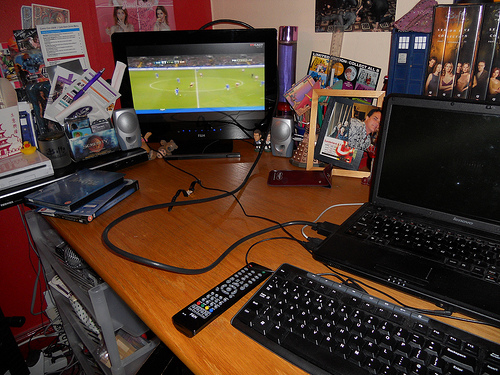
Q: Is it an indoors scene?
A: Yes, it is indoors.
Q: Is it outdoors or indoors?
A: It is indoors.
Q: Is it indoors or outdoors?
A: It is indoors.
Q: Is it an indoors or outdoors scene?
A: It is indoors.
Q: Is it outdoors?
A: No, it is indoors.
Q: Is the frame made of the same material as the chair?
A: No, the frame is made of wood and the chair is made of metal.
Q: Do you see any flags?
A: No, there are no flags.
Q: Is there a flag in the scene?
A: No, there are no flags.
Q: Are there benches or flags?
A: No, there are no flags or benches.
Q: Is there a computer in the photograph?
A: Yes, there is a computer.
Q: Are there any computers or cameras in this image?
A: Yes, there is a computer.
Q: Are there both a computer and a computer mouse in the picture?
A: No, there is a computer but no computer mice.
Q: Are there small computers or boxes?
A: Yes, there is a small computer.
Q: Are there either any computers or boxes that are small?
A: Yes, the computer is small.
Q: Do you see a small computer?
A: Yes, there is a small computer.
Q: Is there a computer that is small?
A: Yes, there is a computer that is small.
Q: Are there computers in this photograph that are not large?
A: Yes, there is a small computer.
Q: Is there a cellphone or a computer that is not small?
A: No, there is a computer but it is small.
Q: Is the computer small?
A: Yes, the computer is small.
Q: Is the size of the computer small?
A: Yes, the computer is small.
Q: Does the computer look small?
A: Yes, the computer is small.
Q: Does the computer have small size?
A: Yes, the computer is small.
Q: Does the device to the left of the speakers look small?
A: Yes, the computer is small.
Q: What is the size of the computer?
A: The computer is small.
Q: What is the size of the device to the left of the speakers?
A: The computer is small.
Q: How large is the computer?
A: The computer is small.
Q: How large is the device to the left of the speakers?
A: The computer is small.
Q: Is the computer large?
A: No, the computer is small.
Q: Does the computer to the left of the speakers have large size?
A: No, the computer is small.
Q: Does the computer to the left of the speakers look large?
A: No, the computer is small.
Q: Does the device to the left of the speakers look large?
A: No, the computer is small.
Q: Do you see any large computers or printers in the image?
A: No, there is a computer but it is small.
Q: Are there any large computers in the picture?
A: No, there is a computer but it is small.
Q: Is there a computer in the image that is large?
A: No, there is a computer but it is small.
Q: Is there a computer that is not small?
A: No, there is a computer but it is small.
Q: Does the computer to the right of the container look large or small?
A: The computer is small.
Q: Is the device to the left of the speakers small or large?
A: The computer is small.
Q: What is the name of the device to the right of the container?
A: The device is a computer.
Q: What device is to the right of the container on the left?
A: The device is a computer.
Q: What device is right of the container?
A: The device is a computer.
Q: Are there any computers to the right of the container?
A: Yes, there is a computer to the right of the container.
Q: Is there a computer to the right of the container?
A: Yes, there is a computer to the right of the container.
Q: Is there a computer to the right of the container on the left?
A: Yes, there is a computer to the right of the container.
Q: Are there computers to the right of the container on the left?
A: Yes, there is a computer to the right of the container.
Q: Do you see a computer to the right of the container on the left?
A: Yes, there is a computer to the right of the container.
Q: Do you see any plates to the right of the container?
A: No, there is a computer to the right of the container.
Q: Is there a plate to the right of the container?
A: No, there is a computer to the right of the container.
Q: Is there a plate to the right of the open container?
A: No, there is a computer to the right of the container.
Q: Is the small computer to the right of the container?
A: Yes, the computer is to the right of the container.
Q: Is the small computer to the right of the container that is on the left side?
A: Yes, the computer is to the right of the container.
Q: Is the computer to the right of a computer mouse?
A: No, the computer is to the right of the container.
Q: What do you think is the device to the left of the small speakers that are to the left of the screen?
A: The device is a computer.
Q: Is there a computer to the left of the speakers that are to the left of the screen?
A: Yes, there is a computer to the left of the speakers.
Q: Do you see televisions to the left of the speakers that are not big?
A: No, there is a computer to the left of the speakers.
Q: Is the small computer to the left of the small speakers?
A: Yes, the computer is to the left of the speakers.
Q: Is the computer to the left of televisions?
A: No, the computer is to the left of the speakers.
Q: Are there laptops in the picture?
A: Yes, there is a laptop.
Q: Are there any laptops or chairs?
A: Yes, there is a laptop.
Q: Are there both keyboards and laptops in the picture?
A: Yes, there are both a laptop and a keyboard.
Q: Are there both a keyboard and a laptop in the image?
A: Yes, there are both a laptop and a keyboard.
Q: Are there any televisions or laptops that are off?
A: Yes, the laptop is off.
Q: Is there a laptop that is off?
A: Yes, there is a laptop that is off.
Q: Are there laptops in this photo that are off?
A: Yes, there is a laptop that is off.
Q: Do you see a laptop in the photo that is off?
A: Yes, there is a laptop that is off.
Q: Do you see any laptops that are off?
A: Yes, there is a laptop that is off.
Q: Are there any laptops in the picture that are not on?
A: Yes, there is a laptop that is off.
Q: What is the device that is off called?
A: The device is a laptop.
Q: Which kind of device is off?
A: The device is a laptop.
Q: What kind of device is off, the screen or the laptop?
A: The laptop is off.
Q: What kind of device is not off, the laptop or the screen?
A: The screen is not off.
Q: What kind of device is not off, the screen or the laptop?
A: The screen is not off.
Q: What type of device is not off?
A: The device is a screen.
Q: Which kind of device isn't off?
A: The device is a screen.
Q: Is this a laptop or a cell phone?
A: This is a laptop.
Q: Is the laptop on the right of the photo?
A: Yes, the laptop is on the right of the image.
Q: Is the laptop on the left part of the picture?
A: No, the laptop is on the right of the image.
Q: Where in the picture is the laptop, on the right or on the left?
A: The laptop is on the right of the image.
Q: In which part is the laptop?
A: The laptop is on the right of the image.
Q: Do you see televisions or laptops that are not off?
A: No, there is a laptop but it is off.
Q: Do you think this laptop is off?
A: Yes, the laptop is off.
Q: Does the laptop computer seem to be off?
A: Yes, the laptop computer is off.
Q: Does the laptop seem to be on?
A: No, the laptop is off.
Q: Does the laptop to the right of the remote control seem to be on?
A: No, the laptop computer is off.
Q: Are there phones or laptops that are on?
A: No, there is a laptop but it is off.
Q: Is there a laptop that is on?
A: No, there is a laptop but it is off.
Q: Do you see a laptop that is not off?
A: No, there is a laptop but it is off.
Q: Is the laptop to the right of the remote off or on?
A: The laptop is off.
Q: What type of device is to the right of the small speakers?
A: The device is a laptop.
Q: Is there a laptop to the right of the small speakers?
A: Yes, there is a laptop to the right of the speakers.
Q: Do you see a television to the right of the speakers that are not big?
A: No, there is a laptop to the right of the speakers.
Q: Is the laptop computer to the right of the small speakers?
A: Yes, the laptop computer is to the right of the speakers.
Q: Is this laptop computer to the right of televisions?
A: No, the laptop computer is to the right of the speakers.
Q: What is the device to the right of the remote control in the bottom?
A: The device is a laptop.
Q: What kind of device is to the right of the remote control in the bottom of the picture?
A: The device is a laptop.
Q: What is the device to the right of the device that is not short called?
A: The device is a laptop.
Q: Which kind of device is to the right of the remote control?
A: The device is a laptop.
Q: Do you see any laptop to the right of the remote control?
A: Yes, there is a laptop to the right of the remote control.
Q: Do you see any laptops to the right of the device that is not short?
A: Yes, there is a laptop to the right of the remote control.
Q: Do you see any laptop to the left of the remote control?
A: No, the laptop is to the right of the remote control.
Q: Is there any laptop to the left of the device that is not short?
A: No, the laptop is to the right of the remote control.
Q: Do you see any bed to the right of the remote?
A: No, there is a laptop to the right of the remote.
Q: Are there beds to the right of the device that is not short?
A: No, there is a laptop to the right of the remote.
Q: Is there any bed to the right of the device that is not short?
A: No, there is a laptop to the right of the remote.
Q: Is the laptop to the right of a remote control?
A: Yes, the laptop is to the right of a remote control.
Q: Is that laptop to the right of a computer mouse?
A: No, the laptop is to the right of a remote control.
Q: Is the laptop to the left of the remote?
A: No, the laptop is to the right of the remote.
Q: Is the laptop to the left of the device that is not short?
A: No, the laptop is to the right of the remote.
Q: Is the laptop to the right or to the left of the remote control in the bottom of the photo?
A: The laptop is to the right of the remote.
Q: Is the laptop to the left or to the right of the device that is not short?
A: The laptop is to the right of the remote.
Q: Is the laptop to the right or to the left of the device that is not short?
A: The laptop is to the right of the remote.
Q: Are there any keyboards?
A: Yes, there is a keyboard.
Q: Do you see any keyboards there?
A: Yes, there is a keyboard.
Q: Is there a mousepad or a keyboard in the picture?
A: Yes, there is a keyboard.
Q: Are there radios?
A: No, there are no radios.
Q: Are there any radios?
A: No, there are no radios.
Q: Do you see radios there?
A: No, there are no radios.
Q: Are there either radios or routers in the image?
A: No, there are no radios or routers.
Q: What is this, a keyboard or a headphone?
A: This is a keyboard.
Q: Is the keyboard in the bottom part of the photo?
A: Yes, the keyboard is in the bottom of the image.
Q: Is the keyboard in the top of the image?
A: No, the keyboard is in the bottom of the image.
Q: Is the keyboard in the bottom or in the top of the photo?
A: The keyboard is in the bottom of the image.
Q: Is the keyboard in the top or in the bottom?
A: The keyboard is in the bottom of the image.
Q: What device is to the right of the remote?
A: The device is a keyboard.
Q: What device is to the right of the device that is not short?
A: The device is a keyboard.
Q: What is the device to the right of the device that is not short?
A: The device is a keyboard.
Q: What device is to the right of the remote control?
A: The device is a keyboard.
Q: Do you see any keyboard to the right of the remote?
A: Yes, there is a keyboard to the right of the remote.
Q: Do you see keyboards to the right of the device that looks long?
A: Yes, there is a keyboard to the right of the remote.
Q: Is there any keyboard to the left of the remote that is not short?
A: No, the keyboard is to the right of the remote.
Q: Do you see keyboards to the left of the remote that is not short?
A: No, the keyboard is to the right of the remote.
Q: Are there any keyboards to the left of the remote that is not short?
A: No, the keyboard is to the right of the remote.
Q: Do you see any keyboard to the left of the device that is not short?
A: No, the keyboard is to the right of the remote.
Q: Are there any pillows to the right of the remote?
A: No, there is a keyboard to the right of the remote.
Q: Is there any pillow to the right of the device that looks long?
A: No, there is a keyboard to the right of the remote.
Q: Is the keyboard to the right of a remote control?
A: Yes, the keyboard is to the right of a remote control.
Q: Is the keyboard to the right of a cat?
A: No, the keyboard is to the right of a remote control.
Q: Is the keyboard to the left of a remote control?
A: No, the keyboard is to the right of a remote control.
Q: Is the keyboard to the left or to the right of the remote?
A: The keyboard is to the right of the remote.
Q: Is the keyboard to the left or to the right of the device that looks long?
A: The keyboard is to the right of the remote.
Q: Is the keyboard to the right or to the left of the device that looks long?
A: The keyboard is to the right of the remote.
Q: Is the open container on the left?
A: Yes, the container is on the left of the image.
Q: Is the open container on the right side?
A: No, the container is on the left of the image.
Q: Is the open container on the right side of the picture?
A: No, the container is on the left of the image.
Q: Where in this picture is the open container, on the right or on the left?
A: The container is on the left of the image.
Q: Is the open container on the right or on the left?
A: The container is on the left of the image.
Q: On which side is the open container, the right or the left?
A: The container is on the left of the image.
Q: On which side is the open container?
A: The container is on the left of the image.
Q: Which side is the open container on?
A: The container is on the left of the image.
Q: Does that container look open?
A: Yes, the container is open.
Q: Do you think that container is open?
A: Yes, the container is open.